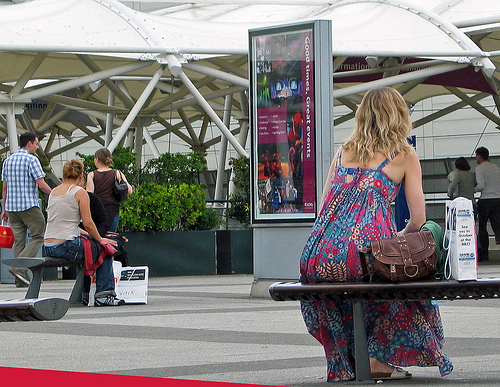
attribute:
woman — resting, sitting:
[309, 79, 445, 378]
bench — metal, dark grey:
[271, 282, 499, 372]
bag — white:
[445, 189, 476, 283]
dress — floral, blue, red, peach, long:
[303, 146, 453, 374]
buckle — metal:
[399, 264, 418, 275]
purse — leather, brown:
[365, 232, 438, 281]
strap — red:
[78, 233, 115, 273]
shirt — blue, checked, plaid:
[6, 157, 43, 211]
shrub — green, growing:
[127, 188, 214, 226]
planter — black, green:
[125, 237, 221, 273]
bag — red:
[3, 226, 14, 249]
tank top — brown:
[93, 167, 120, 219]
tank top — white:
[48, 186, 80, 239]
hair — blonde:
[357, 83, 405, 155]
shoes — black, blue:
[98, 296, 122, 305]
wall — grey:
[417, 125, 500, 148]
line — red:
[2, 366, 246, 385]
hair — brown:
[92, 151, 114, 169]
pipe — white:
[279, 6, 484, 63]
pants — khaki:
[7, 213, 42, 284]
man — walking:
[6, 132, 39, 290]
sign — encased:
[249, 30, 319, 215]